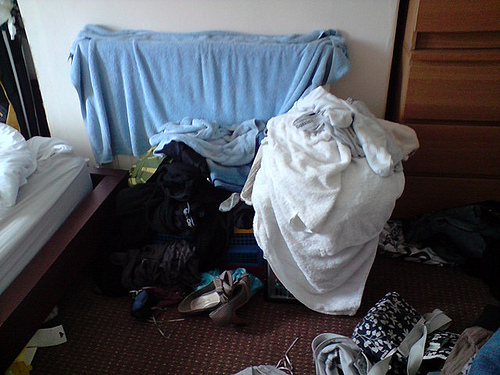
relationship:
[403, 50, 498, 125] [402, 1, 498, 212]
drawer on cabinet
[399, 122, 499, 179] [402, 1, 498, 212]
drawer on cabinet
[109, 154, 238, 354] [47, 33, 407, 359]
these are clothes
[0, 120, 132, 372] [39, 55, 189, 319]
bed on left of room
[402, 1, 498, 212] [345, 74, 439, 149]
cabinet on right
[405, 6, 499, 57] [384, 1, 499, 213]
drawer of cabinet